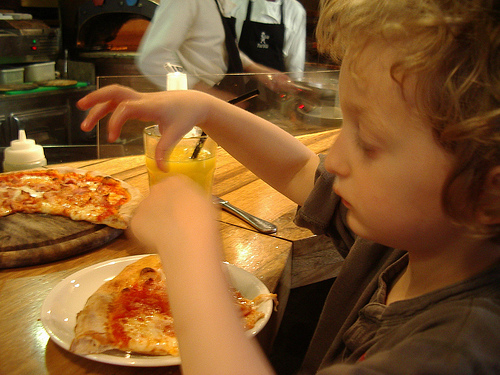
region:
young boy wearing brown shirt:
[95, 12, 478, 357]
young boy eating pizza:
[50, 1, 477, 356]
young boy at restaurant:
[0, 26, 485, 361]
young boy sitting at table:
[76, 34, 486, 366]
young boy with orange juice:
[10, 30, 485, 350]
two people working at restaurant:
[115, 0, 290, 80]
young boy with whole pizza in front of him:
[0, 65, 495, 345]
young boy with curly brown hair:
[335, 20, 495, 345]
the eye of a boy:
[334, 100, 427, 164]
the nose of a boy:
[314, 125, 374, 185]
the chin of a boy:
[317, 200, 398, 242]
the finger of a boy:
[79, 98, 141, 178]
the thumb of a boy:
[151, 103, 195, 173]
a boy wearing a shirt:
[309, 20, 454, 325]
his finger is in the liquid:
[150, 148, 175, 175]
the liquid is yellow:
[193, 168, 206, 185]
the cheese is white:
[137, 324, 152, 340]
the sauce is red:
[130, 289, 150, 300]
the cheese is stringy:
[253, 292, 275, 304]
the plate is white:
[52, 299, 67, 319]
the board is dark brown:
[21, 222, 51, 240]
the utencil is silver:
[238, 203, 279, 240]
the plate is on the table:
[32, 313, 59, 353]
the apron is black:
[246, 26, 263, 46]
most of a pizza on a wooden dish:
[0, 166, 139, 271]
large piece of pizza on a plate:
[40, 248, 270, 366]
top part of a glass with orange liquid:
[142, 123, 216, 188]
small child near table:
[75, 1, 497, 373]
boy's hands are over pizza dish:
[40, 84, 270, 364]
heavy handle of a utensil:
[217, 196, 277, 234]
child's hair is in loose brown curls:
[315, 0, 498, 237]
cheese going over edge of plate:
[252, 287, 279, 314]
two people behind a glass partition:
[96, 1, 340, 156]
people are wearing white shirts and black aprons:
[138, 1, 305, 88]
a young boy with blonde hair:
[73, 3, 481, 366]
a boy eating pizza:
[76, 14, 445, 349]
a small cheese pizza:
[4, 167, 134, 238]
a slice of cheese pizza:
[53, 265, 262, 366]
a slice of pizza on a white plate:
[42, 250, 277, 367]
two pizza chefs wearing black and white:
[143, 0, 311, 93]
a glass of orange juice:
[138, 116, 223, 195]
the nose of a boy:
[320, 139, 355, 184]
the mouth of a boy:
[328, 183, 357, 210]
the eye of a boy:
[350, 108, 389, 167]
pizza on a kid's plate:
[59, 250, 268, 355]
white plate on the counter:
[36, 248, 277, 370]